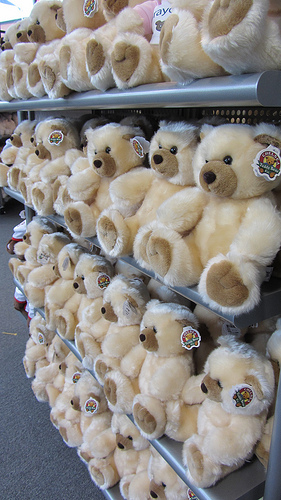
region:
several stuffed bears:
[3, 111, 278, 320]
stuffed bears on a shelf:
[17, 110, 280, 287]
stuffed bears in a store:
[20, 129, 268, 348]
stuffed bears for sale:
[12, 39, 275, 301]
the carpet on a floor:
[3, 416, 48, 495]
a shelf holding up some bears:
[114, 368, 269, 496]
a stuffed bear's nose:
[200, 168, 217, 181]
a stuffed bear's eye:
[221, 153, 234, 164]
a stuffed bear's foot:
[131, 390, 168, 443]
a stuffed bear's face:
[131, 311, 165, 355]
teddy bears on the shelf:
[6, 6, 240, 476]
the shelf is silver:
[137, 428, 236, 493]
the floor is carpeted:
[1, 361, 59, 495]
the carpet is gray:
[4, 367, 75, 497]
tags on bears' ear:
[167, 321, 264, 428]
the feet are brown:
[142, 227, 271, 327]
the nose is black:
[198, 378, 215, 410]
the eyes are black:
[133, 318, 168, 337]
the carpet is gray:
[17, 394, 52, 468]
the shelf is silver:
[61, 83, 273, 113]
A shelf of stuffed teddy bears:
[1, 115, 278, 314]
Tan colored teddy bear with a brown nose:
[131, 117, 279, 316]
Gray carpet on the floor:
[0, 207, 103, 497]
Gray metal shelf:
[155, 425, 279, 497]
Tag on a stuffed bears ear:
[239, 120, 279, 195]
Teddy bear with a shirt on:
[109, 0, 178, 91]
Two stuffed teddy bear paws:
[133, 225, 261, 316]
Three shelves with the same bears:
[0, 116, 278, 498]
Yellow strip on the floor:
[0, 327, 20, 339]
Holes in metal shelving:
[171, 108, 279, 123]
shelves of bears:
[18, 0, 231, 491]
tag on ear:
[229, 382, 263, 409]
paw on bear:
[193, 258, 255, 311]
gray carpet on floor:
[8, 442, 68, 492]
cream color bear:
[102, 307, 193, 420]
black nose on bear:
[198, 384, 211, 397]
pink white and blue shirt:
[140, 3, 181, 46]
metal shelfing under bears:
[93, 83, 262, 109]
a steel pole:
[263, 440, 279, 499]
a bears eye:
[223, 155, 235, 168]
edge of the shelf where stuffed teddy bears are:
[254, 69, 279, 107]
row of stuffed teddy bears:
[4, 0, 275, 67]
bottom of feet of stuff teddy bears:
[87, 41, 148, 86]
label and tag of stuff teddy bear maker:
[228, 384, 258, 408]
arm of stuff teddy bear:
[230, 202, 275, 262]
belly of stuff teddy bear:
[195, 219, 229, 254]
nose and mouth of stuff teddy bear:
[199, 163, 235, 194]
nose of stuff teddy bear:
[201, 171, 216, 181]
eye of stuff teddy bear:
[222, 155, 233, 163]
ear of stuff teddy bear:
[173, 309, 200, 327]